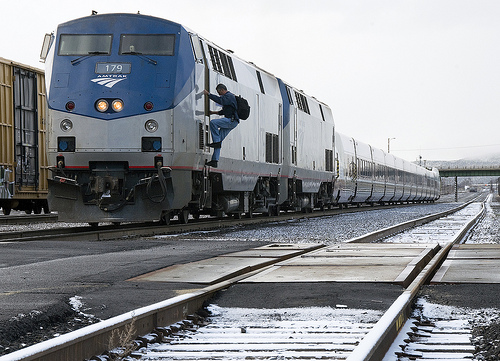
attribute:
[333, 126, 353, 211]
train car — blue, on a track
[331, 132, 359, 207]
train car — on a track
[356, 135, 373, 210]
train car — on a track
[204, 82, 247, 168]
man — entering a train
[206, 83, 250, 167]
man — with a back pack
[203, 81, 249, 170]
train operator — entering the train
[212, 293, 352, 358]
snow — on the train rails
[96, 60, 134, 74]
train number — Amtrak, 179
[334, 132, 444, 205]
passenger cars — attached to the train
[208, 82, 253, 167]
man — wearing a backpack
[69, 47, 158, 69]
windshield wipers — on a train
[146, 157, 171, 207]
wires — on the locomotive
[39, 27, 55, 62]
mirror — on the train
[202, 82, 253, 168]
person — climbing on the train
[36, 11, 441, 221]
train — stopped for repairs, traveling in daytime, stopping for more fuel, transporting many vacationers, stopping for passengers, moving through the city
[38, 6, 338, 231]
train — pulling many cars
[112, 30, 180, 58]
train window — glass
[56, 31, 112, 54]
train window — glass